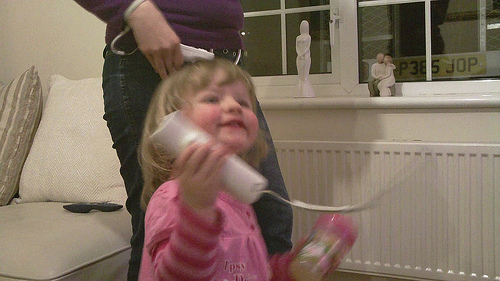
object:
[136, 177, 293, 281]
pink shirt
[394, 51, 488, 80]
sign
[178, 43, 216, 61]
controller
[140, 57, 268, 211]
hair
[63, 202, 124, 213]
remote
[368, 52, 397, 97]
figurine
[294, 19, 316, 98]
figurine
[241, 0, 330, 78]
window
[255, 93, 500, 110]
sill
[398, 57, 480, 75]
numbers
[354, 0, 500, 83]
window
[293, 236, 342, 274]
hand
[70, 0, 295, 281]
father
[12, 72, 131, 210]
pillow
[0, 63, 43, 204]
pillow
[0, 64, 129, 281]
couch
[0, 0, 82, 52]
wall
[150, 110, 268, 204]
controller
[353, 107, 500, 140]
wall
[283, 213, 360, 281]
cup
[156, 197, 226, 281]
stripes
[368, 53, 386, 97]
man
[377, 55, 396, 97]
woman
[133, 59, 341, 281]
blond girl